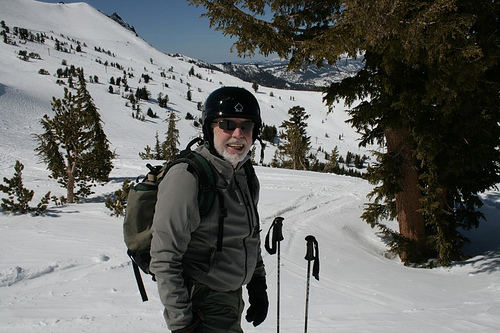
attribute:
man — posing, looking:
[123, 86, 270, 332]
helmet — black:
[201, 86, 263, 152]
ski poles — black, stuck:
[266, 216, 319, 332]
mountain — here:
[0, 1, 416, 174]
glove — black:
[246, 297, 268, 325]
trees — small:
[2, 2, 381, 195]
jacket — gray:
[147, 139, 262, 329]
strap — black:
[131, 263, 151, 303]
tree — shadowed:
[196, 4, 499, 277]